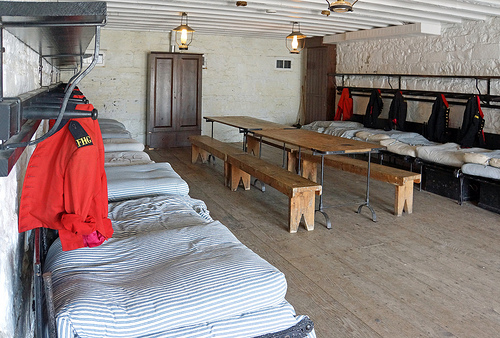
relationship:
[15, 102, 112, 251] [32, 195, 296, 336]
jacket hanging over bed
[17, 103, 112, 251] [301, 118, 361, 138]
jacket hanging over bed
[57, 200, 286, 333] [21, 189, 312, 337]
sheets on bed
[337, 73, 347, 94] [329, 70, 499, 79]
metal posts affixed to bars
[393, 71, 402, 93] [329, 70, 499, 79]
metal posts affixed to bars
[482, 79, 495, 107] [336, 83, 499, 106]
metal posts affixed to bar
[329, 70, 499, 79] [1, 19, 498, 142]
bars on walls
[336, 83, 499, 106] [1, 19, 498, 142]
bar on walls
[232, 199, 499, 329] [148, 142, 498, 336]
floor composed of boards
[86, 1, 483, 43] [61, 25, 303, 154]
vent on wall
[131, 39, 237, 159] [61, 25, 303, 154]
door on wall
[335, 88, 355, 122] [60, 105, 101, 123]
jacket hanging from hook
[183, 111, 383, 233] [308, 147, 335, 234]
table with leg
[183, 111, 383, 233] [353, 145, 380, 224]
table with leg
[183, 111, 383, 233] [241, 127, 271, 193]
table with leg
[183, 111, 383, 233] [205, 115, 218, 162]
table with leg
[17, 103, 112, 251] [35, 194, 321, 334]
jacket hanging over bed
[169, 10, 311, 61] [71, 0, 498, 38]
fixtures hanging from ceiling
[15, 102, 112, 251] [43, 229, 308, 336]
jacket hanging over bed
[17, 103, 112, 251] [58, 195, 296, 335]
jacket over bed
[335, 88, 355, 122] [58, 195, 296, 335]
jacket over bed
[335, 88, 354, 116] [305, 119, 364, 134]
jacket hanging over bed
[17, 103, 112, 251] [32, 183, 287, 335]
jacket hanging over bed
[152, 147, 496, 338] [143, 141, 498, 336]
floor made of wood floor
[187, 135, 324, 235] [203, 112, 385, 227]
bench on both table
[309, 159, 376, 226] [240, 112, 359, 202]
legs of a table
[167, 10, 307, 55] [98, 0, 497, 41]
lights hung from ceiling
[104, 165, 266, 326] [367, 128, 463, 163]
mattresses on cots